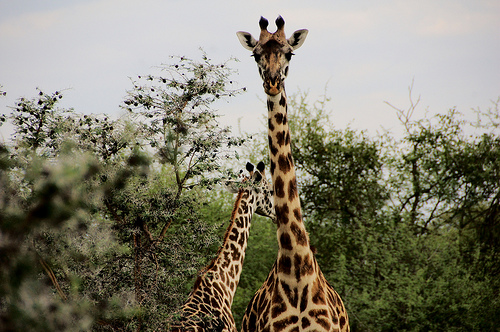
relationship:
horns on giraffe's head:
[250, 13, 298, 35] [229, 1, 354, 318]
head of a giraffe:
[237, 160, 277, 220] [161, 148, 296, 329]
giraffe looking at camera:
[232, 16, 348, 331] [87, 90, 388, 278]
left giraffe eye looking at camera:
[153, 145, 200, 259] [155, 50, 318, 135]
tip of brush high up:
[74, 110, 178, 223] [79, 100, 131, 217]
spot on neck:
[273, 202, 296, 219] [252, 145, 309, 266]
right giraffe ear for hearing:
[317, 114, 377, 231] [311, 253, 371, 292]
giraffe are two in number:
[220, 10, 440, 317] [154, 81, 372, 290]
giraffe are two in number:
[232, 16, 348, 331] [202, 234, 333, 325]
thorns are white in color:
[101, 224, 206, 329] [66, 194, 140, 291]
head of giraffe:
[233, 14, 309, 96] [232, 16, 348, 331]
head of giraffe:
[233, 157, 277, 220] [232, 16, 348, 331]